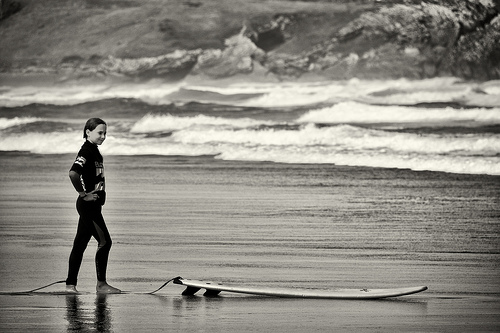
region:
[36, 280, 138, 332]
girl's shadow in sand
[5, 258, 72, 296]
string on woman's foot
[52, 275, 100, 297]
woman's bare feet in sand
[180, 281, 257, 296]
black fins on surf board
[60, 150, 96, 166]
white stripe on black wet suit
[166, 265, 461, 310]
white surf board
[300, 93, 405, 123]
white surf in the water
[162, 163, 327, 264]
wet sand on shore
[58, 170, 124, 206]
girl's hand on her hips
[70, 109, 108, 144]
black hair on girl's head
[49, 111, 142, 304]
Girl near sea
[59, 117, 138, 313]
Girl has right hand on the waist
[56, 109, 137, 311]
Right hand of girl is bend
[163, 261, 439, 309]
White surfboard lying on the sand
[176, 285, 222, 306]
Fins on the tail of surfboard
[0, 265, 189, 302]
Rope of surfboard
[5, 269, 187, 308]
Rope is tied to right ankle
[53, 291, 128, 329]
Reflection of legs of girl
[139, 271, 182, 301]
Rope tied on tip of surfboard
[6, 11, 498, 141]
Water is choppy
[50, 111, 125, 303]
a woman is standing on the beach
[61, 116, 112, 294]
a woman wearing a wetsuit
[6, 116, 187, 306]
a girl tethered to her surfboard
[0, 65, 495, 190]
the waves are coming into shore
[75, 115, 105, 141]
the girl has wet brown hair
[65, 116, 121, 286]
the girl has black wetsuit pants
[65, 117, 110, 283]
the surfer has her hands on her hips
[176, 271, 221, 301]
two skegs are on the surfboard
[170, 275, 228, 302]
the skegs are at the back of the surfboard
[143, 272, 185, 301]
the surfboard is tethered from the back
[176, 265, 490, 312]
surfboard is on the sand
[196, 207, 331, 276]
the sand is wet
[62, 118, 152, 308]
the kid is wearing wet suit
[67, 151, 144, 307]
the wetsuit is black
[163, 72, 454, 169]
the ocean is not calm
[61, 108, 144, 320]
the kid is standing on the sand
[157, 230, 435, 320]
the surfboard is in front of the kid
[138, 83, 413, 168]
there are waves on the water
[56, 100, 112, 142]
the kid has short hair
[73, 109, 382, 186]
the kid is looking at the ocean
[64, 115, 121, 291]
Young girl standing on beach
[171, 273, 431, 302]
Surf board lying in the sand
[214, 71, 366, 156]
Waves in the water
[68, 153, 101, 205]
Right arm of girl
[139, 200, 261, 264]
wet sandy beach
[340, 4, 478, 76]
Large wave in the water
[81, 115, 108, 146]
Wet head of young girl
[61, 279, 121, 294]
wet feet of girl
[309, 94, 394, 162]
Waves in the ocean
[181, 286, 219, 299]
small fins on surf board